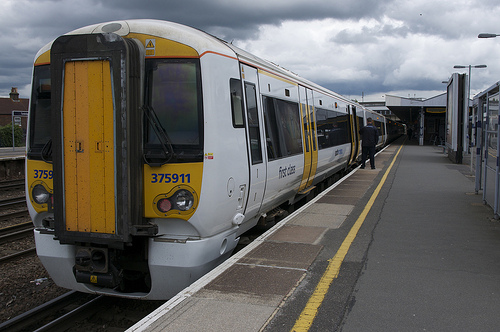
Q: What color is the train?
A: Yellow, black and white.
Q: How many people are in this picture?
A: One.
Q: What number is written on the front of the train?
A: 375911.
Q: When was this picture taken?
A: Daytime.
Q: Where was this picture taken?
A: A train station.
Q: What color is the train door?
A: Yellow.